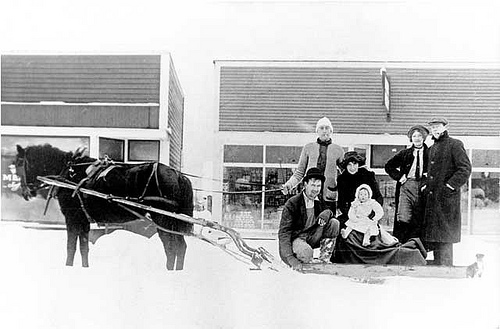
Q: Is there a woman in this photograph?
A: Yes, there is a woman.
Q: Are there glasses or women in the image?
A: Yes, there is a woman.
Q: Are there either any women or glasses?
A: Yes, there is a woman.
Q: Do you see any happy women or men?
A: Yes, there is a happy woman.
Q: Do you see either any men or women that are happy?
A: Yes, the woman is happy.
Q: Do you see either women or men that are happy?
A: Yes, the woman is happy.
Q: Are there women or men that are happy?
A: Yes, the woman is happy.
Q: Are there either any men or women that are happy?
A: Yes, the woman is happy.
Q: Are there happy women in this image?
A: Yes, there is a happy woman.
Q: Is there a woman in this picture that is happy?
A: Yes, there is a woman that is happy.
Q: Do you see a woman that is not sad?
A: Yes, there is a happy woman.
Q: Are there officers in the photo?
A: No, there are no officers.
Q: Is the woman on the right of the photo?
A: Yes, the woman is on the right of the image.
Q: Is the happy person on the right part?
A: Yes, the woman is on the right of the image.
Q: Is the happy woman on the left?
A: No, the woman is on the right of the image.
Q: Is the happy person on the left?
A: No, the woman is on the right of the image.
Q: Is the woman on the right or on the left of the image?
A: The woman is on the right of the image.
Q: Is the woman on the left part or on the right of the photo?
A: The woman is on the right of the image.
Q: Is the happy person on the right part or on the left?
A: The woman is on the right of the image.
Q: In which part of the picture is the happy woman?
A: The woman is on the right of the image.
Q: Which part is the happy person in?
A: The woman is on the right of the image.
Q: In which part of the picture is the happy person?
A: The woman is on the right of the image.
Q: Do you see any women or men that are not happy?
A: No, there is a woman but she is happy.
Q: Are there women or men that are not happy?
A: No, there is a woman but she is happy.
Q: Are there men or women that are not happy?
A: No, there is a woman but she is happy.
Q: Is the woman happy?
A: Yes, the woman is happy.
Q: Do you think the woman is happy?
A: Yes, the woman is happy.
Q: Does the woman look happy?
A: Yes, the woman is happy.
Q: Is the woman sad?
A: No, the woman is happy.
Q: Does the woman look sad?
A: No, the woman is happy.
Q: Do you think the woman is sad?
A: No, the woman is happy.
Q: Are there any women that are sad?
A: No, there is a woman but she is happy.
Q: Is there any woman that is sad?
A: No, there is a woman but she is happy.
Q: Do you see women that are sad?
A: No, there is a woman but she is happy.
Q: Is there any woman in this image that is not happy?
A: No, there is a woman but she is happy.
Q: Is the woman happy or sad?
A: The woman is happy.